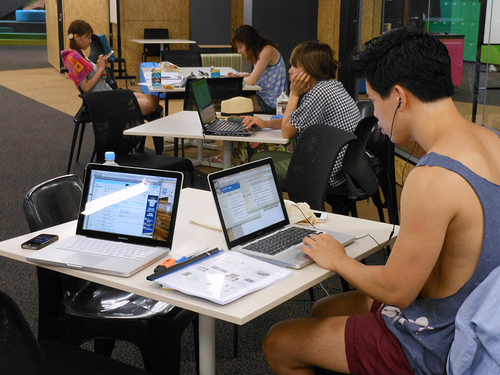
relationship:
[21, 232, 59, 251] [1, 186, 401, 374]
phone on table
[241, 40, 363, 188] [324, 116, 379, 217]
person sitting on chair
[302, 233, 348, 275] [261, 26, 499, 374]
hand of person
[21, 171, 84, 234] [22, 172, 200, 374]
part of chair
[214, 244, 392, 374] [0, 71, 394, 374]
part of carpet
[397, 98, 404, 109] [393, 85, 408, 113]
earphone in ear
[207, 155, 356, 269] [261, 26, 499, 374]
laptop in front of person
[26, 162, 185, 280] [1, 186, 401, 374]
laptop on table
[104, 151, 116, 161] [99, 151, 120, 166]
cap on bottle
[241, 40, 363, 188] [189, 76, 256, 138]
woman looking at laptop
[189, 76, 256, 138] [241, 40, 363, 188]
laptop in front of person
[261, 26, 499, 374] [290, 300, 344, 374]
person wearing shorts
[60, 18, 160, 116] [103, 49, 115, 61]
woman looking at phone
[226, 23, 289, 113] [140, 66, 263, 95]
person sitting at table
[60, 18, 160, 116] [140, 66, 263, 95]
woman sitting at table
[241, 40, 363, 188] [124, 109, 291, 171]
person sitting at table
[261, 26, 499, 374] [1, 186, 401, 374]
person sitting at table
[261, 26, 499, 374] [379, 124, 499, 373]
person wearing shirt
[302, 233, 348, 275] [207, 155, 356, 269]
hand on laptop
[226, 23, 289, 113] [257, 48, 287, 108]
person wearing shirt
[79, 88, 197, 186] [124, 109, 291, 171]
chair next to table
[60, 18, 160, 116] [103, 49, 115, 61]
woman holding phone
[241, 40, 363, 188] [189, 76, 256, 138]
person on laptop